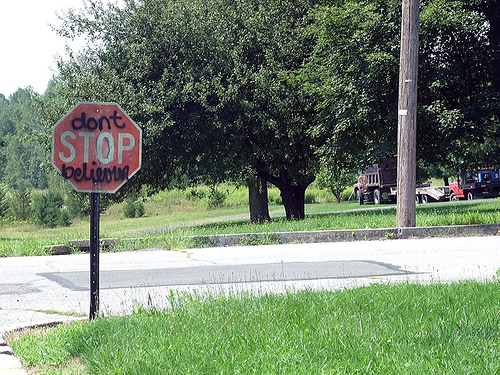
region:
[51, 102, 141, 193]
the red octagon sign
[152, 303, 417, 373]
the lush green grass on the ground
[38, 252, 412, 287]
the darker patch of cement in the road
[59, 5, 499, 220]
the big green tree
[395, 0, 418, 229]
the large wooden telephone pole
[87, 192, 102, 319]
the pole for the stop sign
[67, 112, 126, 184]
the graffiti on the stop sign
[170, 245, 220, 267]
the crack in the road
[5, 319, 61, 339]
the dirt patch by the stop sign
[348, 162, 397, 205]
the dump truck behind the tree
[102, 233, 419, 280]
cement pavement roadway area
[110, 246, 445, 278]
gray cement pavement roadway area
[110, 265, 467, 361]
green grass area in view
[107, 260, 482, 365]
thick green grass area in view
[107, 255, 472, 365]
high green grass area in view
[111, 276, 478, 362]
healthy green grass area in view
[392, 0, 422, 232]
large pole outside in view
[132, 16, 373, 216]
set of green trees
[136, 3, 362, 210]
set of healthy green trees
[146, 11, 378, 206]
big set of green trees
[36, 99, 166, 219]
black graffiti on sign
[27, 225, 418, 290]
a patch on the road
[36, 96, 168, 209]
a red metal street sign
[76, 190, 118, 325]
a black metal pole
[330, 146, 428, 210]
a large work truck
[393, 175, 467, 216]
an empty trailer bed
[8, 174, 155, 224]
a few young evergreens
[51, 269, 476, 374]
an over grown plot of grass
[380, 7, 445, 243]
a thick wood pole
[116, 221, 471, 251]
a tall cement curb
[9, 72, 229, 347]
red stop sign with black grafitti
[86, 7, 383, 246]
two large trees in median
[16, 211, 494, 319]
road in between median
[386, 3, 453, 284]
telephone standing in median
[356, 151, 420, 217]
large dump truck parked on other side of median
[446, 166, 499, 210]
red and blue truck parked on other side of median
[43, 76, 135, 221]
red octagonal sign with white letters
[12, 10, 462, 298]
sun shining in photograph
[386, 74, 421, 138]
white stickers on telephone pole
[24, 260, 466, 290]
segment of road is patched over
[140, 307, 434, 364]
patch of green grass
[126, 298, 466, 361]
patch of healthy green grass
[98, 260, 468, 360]
patch of thick grass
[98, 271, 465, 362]
patch of thick green grass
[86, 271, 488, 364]
patch of healthy thick green grass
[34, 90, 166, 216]
vandalized stop sign in view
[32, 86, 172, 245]
spray painted stop sign in view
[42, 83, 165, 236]
stop sign with black markings